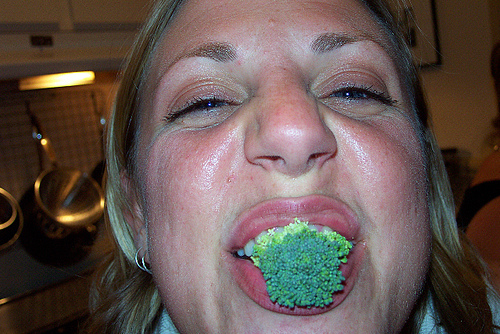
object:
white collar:
[407, 288, 455, 332]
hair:
[94, 0, 493, 334]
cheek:
[356, 138, 423, 232]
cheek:
[150, 127, 225, 254]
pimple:
[268, 17, 278, 24]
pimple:
[225, 176, 234, 184]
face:
[141, 2, 434, 334]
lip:
[228, 194, 363, 250]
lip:
[224, 243, 365, 315]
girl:
[103, 0, 458, 332]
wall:
[417, 0, 499, 176]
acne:
[155, 119, 423, 196]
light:
[20, 69, 96, 91]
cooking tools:
[20, 124, 109, 269]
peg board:
[0, 87, 113, 200]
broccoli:
[248, 218, 353, 309]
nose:
[240, 91, 338, 177]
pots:
[0, 184, 29, 252]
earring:
[134, 244, 155, 273]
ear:
[112, 164, 148, 265]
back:
[0, 132, 105, 334]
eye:
[317, 70, 393, 110]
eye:
[166, 82, 241, 128]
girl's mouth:
[224, 195, 370, 319]